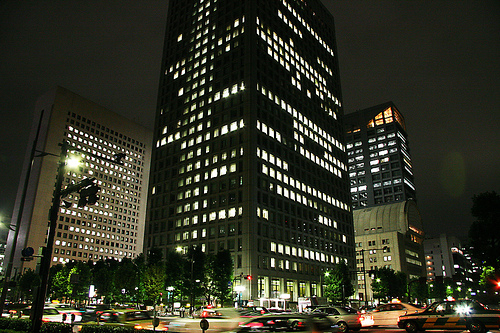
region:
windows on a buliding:
[260, 240, 323, 263]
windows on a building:
[265, 205, 310, 235]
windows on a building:
[250, 137, 290, 167]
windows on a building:
[205, 202, 240, 227]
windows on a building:
[200, 161, 240, 196]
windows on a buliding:
[60, 235, 111, 260]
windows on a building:
[102, 206, 142, 226]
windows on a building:
[110, 180, 140, 195]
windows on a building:
[85, 151, 115, 166]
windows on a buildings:
[370, 147, 396, 168]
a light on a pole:
[61, 148, 80, 179]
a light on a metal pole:
[22, 137, 97, 183]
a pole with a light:
[39, 138, 119, 220]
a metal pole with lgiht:
[29, 131, 94, 176]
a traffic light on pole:
[73, 174, 103, 219]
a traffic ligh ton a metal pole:
[69, 183, 108, 205]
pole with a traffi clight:
[53, 161, 117, 208]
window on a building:
[272, 140, 293, 170]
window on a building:
[316, 206, 330, 225]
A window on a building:
[307, 150, 318, 164]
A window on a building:
[319, 212, 325, 217]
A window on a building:
[264, 234, 274, 248]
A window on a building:
[279, 243, 288, 250]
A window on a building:
[285, 249, 300, 252]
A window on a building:
[302, 248, 317, 263]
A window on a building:
[265, 148, 274, 161]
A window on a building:
[282, 104, 297, 114]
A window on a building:
[305, 83, 315, 102]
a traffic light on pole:
[232, 265, 270, 294]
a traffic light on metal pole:
[234, 265, 267, 287]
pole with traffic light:
[235, 277, 269, 288]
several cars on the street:
[20, 290, 489, 324]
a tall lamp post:
[20, 125, 139, 331]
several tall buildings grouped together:
[7, 0, 490, 271]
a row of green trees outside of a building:
[7, 242, 252, 307]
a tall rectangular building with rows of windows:
[11, 85, 154, 301]